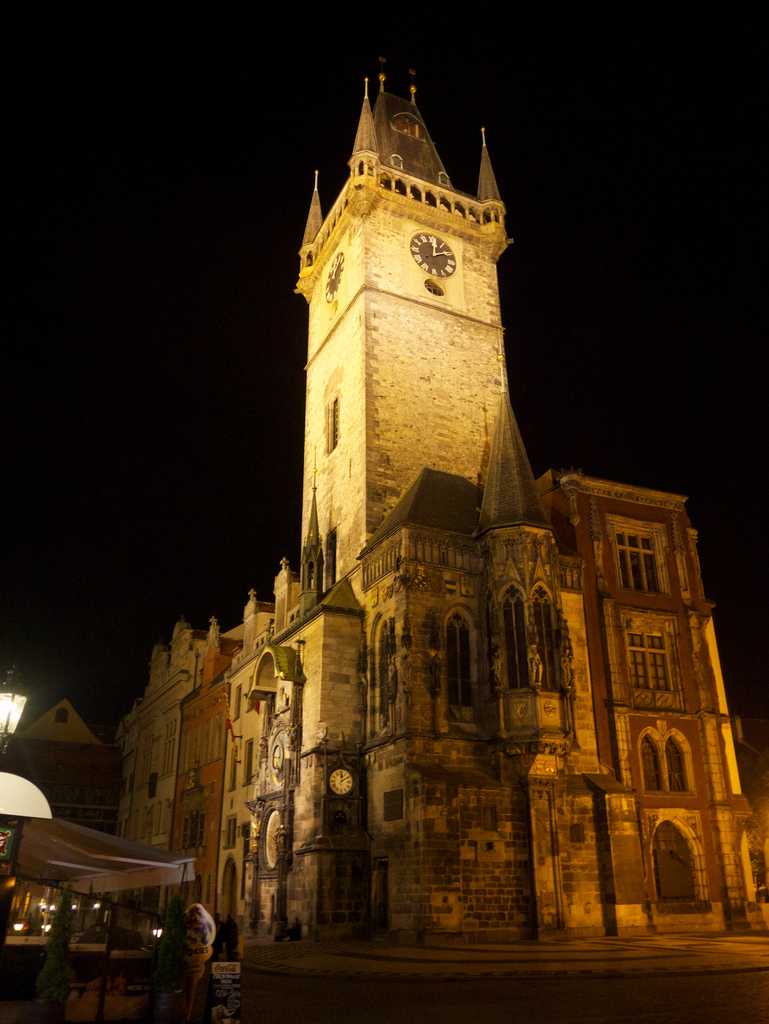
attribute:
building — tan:
[88, 75, 731, 930]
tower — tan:
[221, 87, 625, 500]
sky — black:
[38, 105, 289, 358]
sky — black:
[8, 280, 182, 502]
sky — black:
[138, 383, 262, 539]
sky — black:
[575, 273, 746, 456]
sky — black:
[569, 159, 701, 310]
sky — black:
[78, 222, 261, 406]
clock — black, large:
[394, 183, 475, 285]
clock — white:
[299, 714, 462, 863]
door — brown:
[619, 805, 714, 886]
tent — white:
[14, 775, 229, 984]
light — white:
[0, 733, 53, 847]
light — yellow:
[5, 916, 52, 927]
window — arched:
[601, 702, 764, 816]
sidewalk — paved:
[217, 898, 675, 1000]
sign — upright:
[176, 933, 278, 1021]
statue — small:
[496, 621, 619, 760]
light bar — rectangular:
[10, 683, 29, 779]